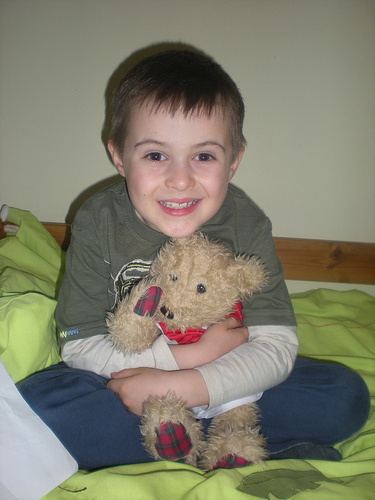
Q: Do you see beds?
A: Yes, there is a bed.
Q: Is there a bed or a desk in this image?
A: Yes, there is a bed.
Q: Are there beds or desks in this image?
A: Yes, there is a bed.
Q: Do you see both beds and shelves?
A: No, there is a bed but no shelves.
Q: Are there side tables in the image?
A: No, there are no side tables.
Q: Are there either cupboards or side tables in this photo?
A: No, there are no side tables or cupboards.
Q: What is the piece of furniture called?
A: The piece of furniture is a bed.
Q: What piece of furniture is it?
A: The piece of furniture is a bed.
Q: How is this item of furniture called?
A: This is a bed.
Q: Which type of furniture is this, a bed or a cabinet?
A: This is a bed.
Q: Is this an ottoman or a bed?
A: This is a bed.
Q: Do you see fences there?
A: No, there are no fences.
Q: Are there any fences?
A: No, there are no fences.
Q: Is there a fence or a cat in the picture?
A: No, there are no fences or cats.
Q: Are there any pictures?
A: No, there are no pictures.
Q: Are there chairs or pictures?
A: No, there are no pictures or chairs.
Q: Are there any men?
A: No, there are no men.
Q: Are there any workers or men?
A: No, there are no men or workers.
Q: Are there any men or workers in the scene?
A: No, there are no men or workers.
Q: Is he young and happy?
A: Yes, the boy is young and happy.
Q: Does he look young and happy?
A: Yes, the boy is young and happy.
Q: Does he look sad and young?
A: No, the boy is young but happy.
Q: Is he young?
A: Yes, the boy is young.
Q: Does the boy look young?
A: Yes, the boy is young.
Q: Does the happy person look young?
A: Yes, the boy is young.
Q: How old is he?
A: The boy is young.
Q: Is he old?
A: No, the boy is young.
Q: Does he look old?
A: No, the boy is young.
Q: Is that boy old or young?
A: The boy is young.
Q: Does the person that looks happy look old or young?
A: The boy is young.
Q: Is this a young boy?
A: Yes, this is a young boy.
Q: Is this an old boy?
A: No, this is a young boy.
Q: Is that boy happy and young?
A: Yes, the boy is happy and young.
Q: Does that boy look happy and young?
A: Yes, the boy is happy and young.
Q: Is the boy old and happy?
A: No, the boy is happy but young.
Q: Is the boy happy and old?
A: No, the boy is happy but young.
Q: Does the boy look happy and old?
A: No, the boy is happy but young.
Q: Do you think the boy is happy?
A: Yes, the boy is happy.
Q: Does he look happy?
A: Yes, the boy is happy.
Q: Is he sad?
A: No, the boy is happy.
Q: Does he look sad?
A: No, the boy is happy.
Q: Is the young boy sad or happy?
A: The boy is happy.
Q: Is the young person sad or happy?
A: The boy is happy.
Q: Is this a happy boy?
A: Yes, this is a happy boy.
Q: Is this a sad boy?
A: No, this is a happy boy.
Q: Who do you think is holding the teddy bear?
A: The boy is holding the teddy bear.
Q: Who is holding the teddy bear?
A: The boy is holding the teddy bear.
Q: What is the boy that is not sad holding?
A: The boy is holding the teddy bear.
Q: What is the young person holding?
A: The boy is holding the teddy bear.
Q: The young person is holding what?
A: The boy is holding the teddy bear.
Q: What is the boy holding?
A: The boy is holding the teddy bear.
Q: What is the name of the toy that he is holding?
A: The toy is a teddy bear.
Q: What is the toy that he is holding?
A: The toy is a teddy bear.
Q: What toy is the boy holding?
A: The boy is holding the teddy bear.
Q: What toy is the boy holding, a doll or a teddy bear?
A: The boy is holding a teddy bear.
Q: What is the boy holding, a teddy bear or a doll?
A: The boy is holding a teddy bear.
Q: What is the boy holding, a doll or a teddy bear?
A: The boy is holding a teddy bear.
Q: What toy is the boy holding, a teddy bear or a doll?
A: The boy is holding a teddy bear.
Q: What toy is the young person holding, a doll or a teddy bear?
A: The boy is holding a teddy bear.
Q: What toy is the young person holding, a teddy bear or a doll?
A: The boy is holding a teddy bear.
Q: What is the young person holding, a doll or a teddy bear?
A: The boy is holding a teddy bear.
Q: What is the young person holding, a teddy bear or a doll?
A: The boy is holding a teddy bear.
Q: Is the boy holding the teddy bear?
A: Yes, the boy is holding the teddy bear.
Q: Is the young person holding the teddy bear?
A: Yes, the boy is holding the teddy bear.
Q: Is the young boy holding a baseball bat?
A: No, the boy is holding the teddy bear.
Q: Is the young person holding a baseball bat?
A: No, the boy is holding the teddy bear.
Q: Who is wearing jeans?
A: The boy is wearing jeans.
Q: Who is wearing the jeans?
A: The boy is wearing jeans.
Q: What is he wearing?
A: The boy is wearing jeans.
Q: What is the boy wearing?
A: The boy is wearing jeans.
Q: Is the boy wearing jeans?
A: Yes, the boy is wearing jeans.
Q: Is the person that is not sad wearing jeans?
A: Yes, the boy is wearing jeans.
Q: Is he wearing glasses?
A: No, the boy is wearing jeans.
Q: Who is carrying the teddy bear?
A: The boy is carrying the teddy bear.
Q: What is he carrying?
A: The boy is carrying a teddy bear.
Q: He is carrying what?
A: The boy is carrying a teddy bear.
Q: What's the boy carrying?
A: The boy is carrying a teddy bear.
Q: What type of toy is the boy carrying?
A: The boy is carrying a teddy bear.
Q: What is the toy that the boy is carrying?
A: The toy is a teddy bear.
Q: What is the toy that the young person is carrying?
A: The toy is a teddy bear.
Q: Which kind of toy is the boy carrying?
A: The boy is carrying a teddy bear.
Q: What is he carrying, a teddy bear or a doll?
A: The boy is carrying a teddy bear.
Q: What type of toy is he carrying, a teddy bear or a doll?
A: The boy is carrying a teddy bear.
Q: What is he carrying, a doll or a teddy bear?
A: The boy is carrying a teddy bear.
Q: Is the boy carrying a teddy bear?
A: Yes, the boy is carrying a teddy bear.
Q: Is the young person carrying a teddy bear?
A: Yes, the boy is carrying a teddy bear.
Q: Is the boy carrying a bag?
A: No, the boy is carrying a teddy bear.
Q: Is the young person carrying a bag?
A: No, the boy is carrying a teddy bear.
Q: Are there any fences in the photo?
A: No, there are no fences.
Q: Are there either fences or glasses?
A: No, there are no fences or glasses.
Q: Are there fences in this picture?
A: No, there are no fences.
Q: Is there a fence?
A: No, there are no fences.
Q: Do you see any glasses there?
A: No, there are no glasses.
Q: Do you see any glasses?
A: No, there are no glasses.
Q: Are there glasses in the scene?
A: No, there are no glasses.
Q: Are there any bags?
A: No, there are no bags.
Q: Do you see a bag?
A: No, there are no bags.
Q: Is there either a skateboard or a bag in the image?
A: No, there are no bags or skateboards.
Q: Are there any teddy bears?
A: Yes, there is a teddy bear.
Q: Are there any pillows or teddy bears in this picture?
A: Yes, there is a teddy bear.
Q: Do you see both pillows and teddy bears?
A: No, there is a teddy bear but no pillows.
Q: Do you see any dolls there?
A: No, there are no dolls.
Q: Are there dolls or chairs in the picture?
A: No, there are no dolls or chairs.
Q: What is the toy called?
A: The toy is a teddy bear.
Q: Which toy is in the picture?
A: The toy is a teddy bear.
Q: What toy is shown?
A: The toy is a teddy bear.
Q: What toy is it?
A: The toy is a teddy bear.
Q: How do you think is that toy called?
A: This is a teddy bear.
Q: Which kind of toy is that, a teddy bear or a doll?
A: This is a teddy bear.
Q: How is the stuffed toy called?
A: The toy is a teddy bear.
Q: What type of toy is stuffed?
A: The toy is a teddy bear.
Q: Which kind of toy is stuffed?
A: The toy is a teddy bear.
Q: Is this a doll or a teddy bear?
A: This is a teddy bear.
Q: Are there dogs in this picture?
A: No, there are no dogs.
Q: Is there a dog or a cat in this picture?
A: No, there are no dogs or cats.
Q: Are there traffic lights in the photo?
A: No, there are no traffic lights.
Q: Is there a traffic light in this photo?
A: No, there are no traffic lights.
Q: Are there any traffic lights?
A: No, there are no traffic lights.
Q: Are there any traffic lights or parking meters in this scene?
A: No, there are no traffic lights or parking meters.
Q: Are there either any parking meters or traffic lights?
A: No, there are no traffic lights or parking meters.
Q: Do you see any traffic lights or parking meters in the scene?
A: No, there are no traffic lights or parking meters.